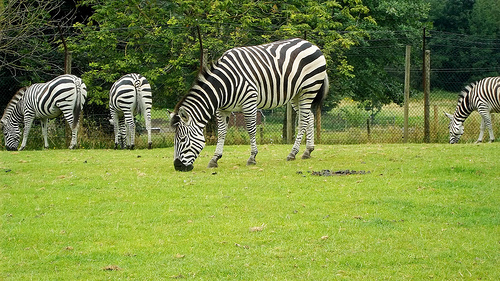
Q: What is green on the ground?
A: The grass.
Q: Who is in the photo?
A: The zebras.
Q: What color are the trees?
A: Green.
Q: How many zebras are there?
A: Four.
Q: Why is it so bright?
A: Sunny.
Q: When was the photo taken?
A: Day time.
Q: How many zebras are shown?
A: Four.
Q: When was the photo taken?
A: Daytime.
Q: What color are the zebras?
A: Black and white.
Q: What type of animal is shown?
A: Zebras.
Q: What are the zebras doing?
A: Eating.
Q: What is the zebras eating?
A: Grass.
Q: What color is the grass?
A: Green.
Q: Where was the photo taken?
A: In a park.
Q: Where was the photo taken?
A: In a zoo.